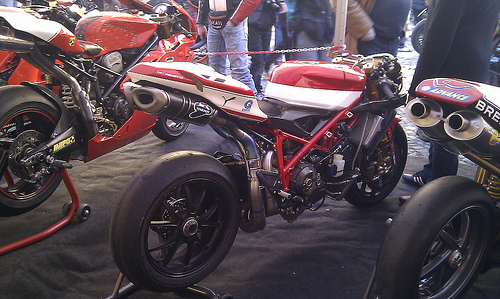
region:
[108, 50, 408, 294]
this is a red motorcycle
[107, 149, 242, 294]
this is a wheel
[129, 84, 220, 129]
this is a pipe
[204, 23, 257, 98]
these are his blue jeans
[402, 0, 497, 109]
this is a black jacket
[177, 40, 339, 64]
this is a chain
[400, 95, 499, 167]
these are two pipes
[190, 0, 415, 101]
these are people standing around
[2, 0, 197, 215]
this is another motorcycle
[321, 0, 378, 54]
this is a brown jacket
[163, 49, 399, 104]
The motorcycle is red and white.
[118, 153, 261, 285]
Back wheel of the motorcycle.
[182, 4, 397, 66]
People standing in front of the motorcycle.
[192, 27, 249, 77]
The person is wearing jeans.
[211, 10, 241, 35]
The man has his hand in pocket.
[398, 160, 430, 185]
The tennis shoes has white stripes.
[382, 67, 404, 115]
Handle on the motorcycle.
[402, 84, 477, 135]
Muffler on the back of the motorcycle.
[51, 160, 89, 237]
A red stand on the ground.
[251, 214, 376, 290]
Black covering on the floor.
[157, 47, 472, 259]
motorcycles that are inside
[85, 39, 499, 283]
motorcycles that are on display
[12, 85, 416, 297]
old motorcycles on display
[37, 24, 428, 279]
red and white motorcycles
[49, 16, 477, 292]
red and white motorcycles on display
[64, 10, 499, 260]
red and white motorcycles on stands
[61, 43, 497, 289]
motorcycles on stands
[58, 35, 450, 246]
a display of motorcycles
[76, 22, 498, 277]
a display of red and white motorcycles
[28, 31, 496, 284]
a display of bikes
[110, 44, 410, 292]
Red and white motorbike.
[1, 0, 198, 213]
A red colored motorbike.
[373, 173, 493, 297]
A black colored tire.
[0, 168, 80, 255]
A red metal bar.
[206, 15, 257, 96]
A pair of light blue jeans.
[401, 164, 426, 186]
Black and white shoe.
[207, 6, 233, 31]
A dark blue fanny pack.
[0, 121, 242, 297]
Gray colored floor covering.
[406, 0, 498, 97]
A black colored jacket.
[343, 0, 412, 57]
A person standing up.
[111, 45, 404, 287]
A motorcycle near the people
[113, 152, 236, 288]
The back wheel of the motorcycle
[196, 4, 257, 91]
A man standing near the motorcycles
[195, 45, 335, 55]
A chain blocking off the motorcycles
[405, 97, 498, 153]
Exhaust pipes on the motorcycle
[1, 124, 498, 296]
The ground beneath the motorcycles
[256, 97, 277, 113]
The seat of the motorcycle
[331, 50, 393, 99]
Handlebars on the motorcycle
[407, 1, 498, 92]
The person is wearing a black coat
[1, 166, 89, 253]
A wheeled clamp holding the motorcycle